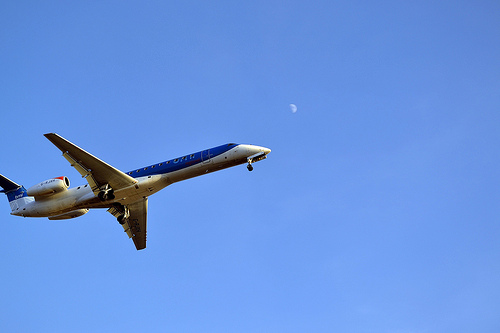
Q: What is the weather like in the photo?
A: It is clear.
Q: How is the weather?
A: It is clear.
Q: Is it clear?
A: Yes, it is clear.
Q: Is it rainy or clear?
A: It is clear.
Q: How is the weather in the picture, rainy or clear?
A: It is clear.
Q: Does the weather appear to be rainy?
A: No, it is clear.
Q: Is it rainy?
A: No, it is clear.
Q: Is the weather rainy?
A: No, it is clear.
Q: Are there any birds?
A: No, there are no birds.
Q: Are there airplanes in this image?
A: Yes, there is an airplane.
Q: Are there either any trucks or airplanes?
A: Yes, there is an airplane.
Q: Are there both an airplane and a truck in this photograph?
A: No, there is an airplane but no trucks.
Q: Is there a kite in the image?
A: No, there are no kites.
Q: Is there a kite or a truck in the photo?
A: No, there are no kites or trucks.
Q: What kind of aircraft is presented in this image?
A: The aircraft is an airplane.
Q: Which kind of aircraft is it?
A: The aircraft is an airplane.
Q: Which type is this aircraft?
A: This is an airplane.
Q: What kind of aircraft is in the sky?
A: The aircraft is an airplane.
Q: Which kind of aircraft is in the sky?
A: The aircraft is an airplane.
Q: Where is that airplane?
A: The airplane is in the sky.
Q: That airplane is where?
A: The airplane is in the sky.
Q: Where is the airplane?
A: The airplane is in the sky.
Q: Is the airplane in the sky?
A: Yes, the airplane is in the sky.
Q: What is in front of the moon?
A: The plane is in front of the moon.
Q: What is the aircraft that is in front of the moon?
A: The aircraft is an airplane.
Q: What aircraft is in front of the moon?
A: The aircraft is an airplane.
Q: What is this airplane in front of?
A: The airplane is in front of the moon.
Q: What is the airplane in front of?
A: The airplane is in front of the moon.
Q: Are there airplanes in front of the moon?
A: Yes, there is an airplane in front of the moon.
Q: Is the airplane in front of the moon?
A: Yes, the airplane is in front of the moon.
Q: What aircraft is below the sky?
A: The aircraft is an airplane.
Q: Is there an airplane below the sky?
A: Yes, there is an airplane below the sky.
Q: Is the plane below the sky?
A: Yes, the plane is below the sky.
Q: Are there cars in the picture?
A: No, there are no cars.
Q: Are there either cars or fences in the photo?
A: No, there are no cars or fences.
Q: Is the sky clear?
A: Yes, the sky is clear.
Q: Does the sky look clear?
A: Yes, the sky is clear.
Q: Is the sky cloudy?
A: No, the sky is clear.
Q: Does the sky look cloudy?
A: No, the sky is clear.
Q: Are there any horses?
A: No, there are no horses.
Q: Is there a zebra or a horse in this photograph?
A: No, there are no horses or zebras.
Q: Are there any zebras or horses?
A: No, there are no horses or zebras.